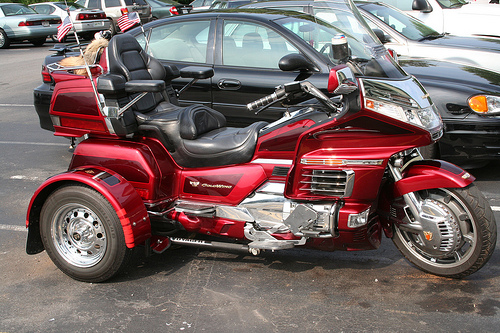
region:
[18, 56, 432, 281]
red bike parked on street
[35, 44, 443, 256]
bike with no one on it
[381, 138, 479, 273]
black tire under car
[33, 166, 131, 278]
silver rim on tire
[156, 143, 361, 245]
red and silver body of bike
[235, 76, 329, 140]
silver handle on bike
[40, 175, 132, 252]
back tire of bike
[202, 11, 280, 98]
black car next to bike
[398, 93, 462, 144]
front of the bike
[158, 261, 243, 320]
blakc street beneath the bike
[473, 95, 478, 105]
the light is yellow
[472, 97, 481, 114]
the light is yellow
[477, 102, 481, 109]
the light is yellow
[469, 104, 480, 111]
the light is yellow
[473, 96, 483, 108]
the light is yellow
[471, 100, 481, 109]
the light is yellow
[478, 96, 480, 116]
the light is yellow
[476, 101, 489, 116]
the light is yellow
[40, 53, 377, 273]
this is a motorbike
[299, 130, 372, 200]
the motorbike is red in color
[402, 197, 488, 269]
the front wheel is small in size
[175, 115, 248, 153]
the seat is leather like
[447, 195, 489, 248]
the wheel is black in color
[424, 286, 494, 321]
the road is wet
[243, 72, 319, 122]
this is the steering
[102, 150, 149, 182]
the motorbike is shiny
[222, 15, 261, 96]
this is a car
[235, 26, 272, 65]
the window is closed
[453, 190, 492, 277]
part of a wheel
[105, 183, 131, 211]
part of a guard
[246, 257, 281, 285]
part of a shade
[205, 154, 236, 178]
edge of a seat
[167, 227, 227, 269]
part of a metal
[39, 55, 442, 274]
this is a motorbike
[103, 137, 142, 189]
the motorbike is red in color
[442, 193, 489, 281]
this is a wheel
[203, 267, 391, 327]
this is a road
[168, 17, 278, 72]
this is a car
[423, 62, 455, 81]
the car is black in color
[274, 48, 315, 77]
this is a side mirror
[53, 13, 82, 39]
this is a flag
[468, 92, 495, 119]
this is the head light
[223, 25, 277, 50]
this is the window